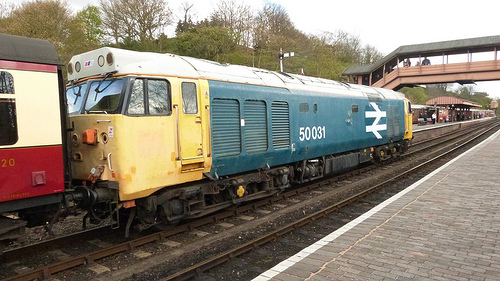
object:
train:
[0, 37, 414, 233]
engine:
[337, 78, 416, 152]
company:
[363, 102, 399, 140]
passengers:
[452, 103, 475, 118]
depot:
[412, 90, 495, 137]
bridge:
[343, 37, 500, 90]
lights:
[275, 48, 298, 58]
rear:
[294, 75, 417, 161]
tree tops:
[204, 1, 303, 25]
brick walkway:
[412, 116, 493, 144]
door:
[171, 80, 207, 167]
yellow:
[123, 129, 158, 173]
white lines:
[364, 110, 388, 117]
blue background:
[205, 80, 408, 179]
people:
[423, 109, 452, 119]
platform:
[409, 93, 497, 131]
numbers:
[295, 124, 328, 142]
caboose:
[0, 26, 74, 214]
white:
[162, 59, 186, 73]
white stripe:
[413, 117, 495, 131]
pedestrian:
[419, 54, 432, 69]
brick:
[419, 133, 431, 136]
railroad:
[13, 118, 500, 281]